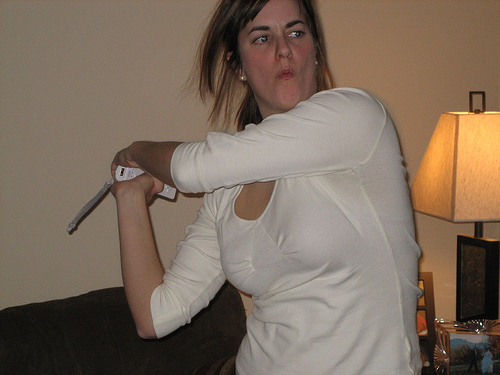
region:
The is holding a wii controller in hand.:
[56, 142, 186, 233]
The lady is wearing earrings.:
[226, 69, 251, 92]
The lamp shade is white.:
[417, 97, 492, 232]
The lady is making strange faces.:
[226, 9, 348, 130]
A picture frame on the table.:
[438, 326, 496, 371]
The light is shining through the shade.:
[431, 114, 490, 221]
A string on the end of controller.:
[63, 184, 113, 231]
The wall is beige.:
[38, 17, 223, 162]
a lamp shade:
[413, 93, 498, 221]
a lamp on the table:
[419, 75, 493, 345]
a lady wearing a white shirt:
[103, 10, 423, 372]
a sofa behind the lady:
[6, 273, 272, 372]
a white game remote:
[115, 158, 181, 201]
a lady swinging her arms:
[132, 29, 429, 364]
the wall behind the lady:
[2, 17, 122, 338]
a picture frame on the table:
[418, 275, 435, 338]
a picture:
[452, 328, 497, 365]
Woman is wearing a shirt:
[137, 84, 437, 374]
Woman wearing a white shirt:
[142, 70, 429, 372]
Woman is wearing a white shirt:
[142, 80, 428, 374]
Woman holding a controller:
[57, 152, 184, 234]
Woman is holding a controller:
[56, 154, 183, 239]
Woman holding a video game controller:
[60, 151, 192, 238]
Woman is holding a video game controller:
[61, 157, 186, 238]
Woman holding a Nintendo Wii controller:
[62, 145, 190, 245]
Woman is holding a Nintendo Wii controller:
[54, 155, 194, 242]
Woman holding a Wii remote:
[68, 0, 424, 372]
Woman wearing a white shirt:
[107, 0, 439, 374]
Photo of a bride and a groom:
[446, 325, 498, 374]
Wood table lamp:
[405, 87, 498, 322]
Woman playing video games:
[67, 0, 429, 374]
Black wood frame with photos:
[410, 268, 440, 373]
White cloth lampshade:
[407, 107, 498, 227]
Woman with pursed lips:
[107, 0, 437, 374]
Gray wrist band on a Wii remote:
[61, 177, 111, 237]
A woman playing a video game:
[69, 0, 424, 374]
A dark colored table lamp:
[412, 90, 499, 321]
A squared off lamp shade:
[411, 110, 498, 221]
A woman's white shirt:
[151, 85, 422, 372]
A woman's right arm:
[117, 196, 225, 338]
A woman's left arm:
[108, 96, 386, 196]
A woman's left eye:
[285, 28, 308, 40]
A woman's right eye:
[249, 34, 271, 46]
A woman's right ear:
[225, 53, 247, 83]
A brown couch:
[0, 284, 245, 374]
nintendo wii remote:
[46, 129, 195, 253]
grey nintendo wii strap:
[61, 165, 118, 242]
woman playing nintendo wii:
[45, 5, 460, 369]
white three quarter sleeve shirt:
[110, 98, 452, 370]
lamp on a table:
[394, 60, 498, 336]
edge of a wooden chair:
[399, 265, 443, 372]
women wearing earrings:
[200, 3, 360, 118]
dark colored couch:
[2, 241, 307, 373]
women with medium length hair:
[175, 7, 357, 131]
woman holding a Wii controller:
[101, 158, 181, 200]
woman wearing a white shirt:
[119, 68, 432, 368]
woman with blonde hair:
[176, 1, 359, 137]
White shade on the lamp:
[406, 82, 498, 233]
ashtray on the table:
[447, 305, 494, 347]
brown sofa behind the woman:
[3, 273, 246, 372]